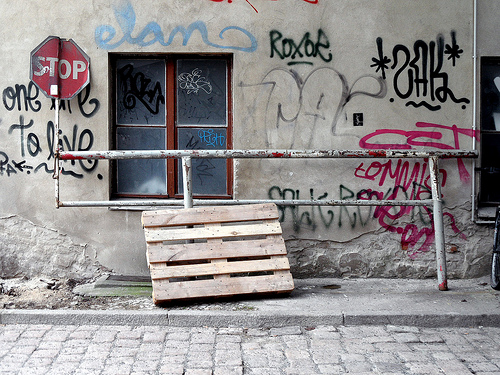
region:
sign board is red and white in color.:
[28, 29, 100, 103]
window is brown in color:
[106, 50, 242, 205]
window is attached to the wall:
[100, 51, 255, 211]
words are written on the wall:
[262, 20, 461, 154]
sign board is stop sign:
[35, 34, 92, 94]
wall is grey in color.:
[17, 11, 81, 40]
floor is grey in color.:
[168, 329, 346, 361]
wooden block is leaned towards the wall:
[133, 221, 243, 307]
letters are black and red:
[276, 37, 456, 156]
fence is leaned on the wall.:
[271, 127, 480, 205]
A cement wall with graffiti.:
[1, 1, 499, 260]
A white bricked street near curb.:
[0, 325, 497, 373]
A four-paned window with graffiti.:
[106, 50, 232, 204]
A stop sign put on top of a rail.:
[28, 34, 91, 209]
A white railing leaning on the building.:
[53, 144, 484, 289]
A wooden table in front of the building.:
[141, 202, 296, 302]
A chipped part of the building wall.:
[1, 204, 107, 317]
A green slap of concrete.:
[76, 279, 153, 298]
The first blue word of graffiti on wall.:
[86, 0, 258, 55]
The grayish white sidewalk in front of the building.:
[290, 290, 499, 327]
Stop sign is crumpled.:
[24, 31, 94, 107]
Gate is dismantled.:
[31, 129, 483, 301]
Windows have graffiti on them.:
[117, 47, 234, 196]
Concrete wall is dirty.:
[1, 32, 492, 288]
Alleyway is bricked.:
[0, 320, 497, 370]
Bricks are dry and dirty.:
[0, 312, 499, 372]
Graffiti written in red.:
[341, 105, 476, 270]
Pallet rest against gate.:
[130, 182, 306, 319]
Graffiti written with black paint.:
[352, 30, 475, 123]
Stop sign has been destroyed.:
[15, 29, 104, 116]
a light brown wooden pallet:
[136, 202, 301, 300]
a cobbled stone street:
[1, 319, 498, 374]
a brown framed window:
[103, 49, 238, 204]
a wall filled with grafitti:
[2, 2, 499, 286]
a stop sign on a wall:
[26, 33, 93, 108]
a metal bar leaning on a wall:
[49, 97, 476, 300]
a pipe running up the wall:
[468, 2, 495, 233]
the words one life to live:
[5, 82, 100, 172]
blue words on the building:
[88, 2, 264, 54]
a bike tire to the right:
[490, 200, 499, 296]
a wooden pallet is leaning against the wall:
[141, 199, 296, 307]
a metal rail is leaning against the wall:
[50, 137, 480, 292]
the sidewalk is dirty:
[1, 273, 499, 327]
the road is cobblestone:
[1, 320, 499, 373]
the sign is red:
[33, 31, 91, 111]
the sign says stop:
[32, 52, 85, 86]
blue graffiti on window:
[198, 127, 225, 148]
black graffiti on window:
[116, 61, 165, 123]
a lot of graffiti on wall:
[1, 1, 477, 274]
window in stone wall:
[103, 50, 239, 204]